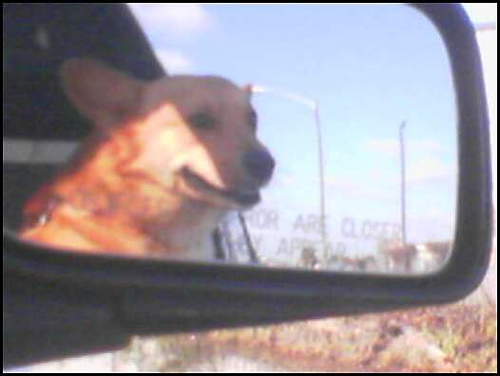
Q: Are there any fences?
A: No, there are no fences.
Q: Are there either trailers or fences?
A: No, there are no fences or trailers.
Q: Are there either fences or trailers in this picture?
A: No, there are no fences or trailers.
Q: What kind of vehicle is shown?
A: The vehicle is a car.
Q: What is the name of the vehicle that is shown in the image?
A: The vehicle is a car.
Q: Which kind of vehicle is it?
A: The vehicle is a car.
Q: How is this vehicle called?
A: This is a car.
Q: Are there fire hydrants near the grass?
A: No, there is a car near the grass.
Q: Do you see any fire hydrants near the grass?
A: No, there is a car near the grass.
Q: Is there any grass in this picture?
A: Yes, there is grass.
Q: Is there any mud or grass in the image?
A: Yes, there is grass.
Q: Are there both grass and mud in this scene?
A: No, there is grass but no mud.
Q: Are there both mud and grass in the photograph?
A: No, there is grass but no mud.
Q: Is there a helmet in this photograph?
A: No, there are no helmets.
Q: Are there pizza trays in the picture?
A: No, there are no pizza trays.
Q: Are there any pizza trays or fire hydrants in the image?
A: No, there are no pizza trays or fire hydrants.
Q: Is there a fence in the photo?
A: No, there are no fences.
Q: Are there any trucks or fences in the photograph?
A: No, there are no fences or trucks.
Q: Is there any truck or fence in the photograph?
A: No, there are no fences or trucks.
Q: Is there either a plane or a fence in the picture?
A: No, there are no fences or airplanes.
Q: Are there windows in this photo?
A: Yes, there is a window.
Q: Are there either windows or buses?
A: Yes, there is a window.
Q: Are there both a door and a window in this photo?
A: No, there is a window but no doors.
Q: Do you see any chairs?
A: No, there are no chairs.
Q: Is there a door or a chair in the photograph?
A: No, there are no chairs or doors.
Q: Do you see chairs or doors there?
A: No, there are no chairs or doors.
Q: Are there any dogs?
A: Yes, there is a dog.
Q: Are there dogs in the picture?
A: Yes, there is a dog.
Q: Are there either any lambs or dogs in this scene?
A: Yes, there is a dog.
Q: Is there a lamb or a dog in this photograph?
A: Yes, there is a dog.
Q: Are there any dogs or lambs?
A: Yes, there is a dog.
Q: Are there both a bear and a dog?
A: No, there is a dog but no bears.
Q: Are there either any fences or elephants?
A: No, there are no fences or elephants.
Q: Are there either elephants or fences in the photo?
A: No, there are no fences or elephants.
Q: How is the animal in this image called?
A: The animal is a dog.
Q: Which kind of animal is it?
A: The animal is a dog.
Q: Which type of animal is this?
A: This is a dog.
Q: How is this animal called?
A: This is a dog.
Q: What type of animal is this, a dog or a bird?
A: This is a dog.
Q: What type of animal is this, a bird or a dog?
A: This is a dog.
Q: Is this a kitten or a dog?
A: This is a dog.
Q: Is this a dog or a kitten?
A: This is a dog.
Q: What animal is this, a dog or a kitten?
A: This is a dog.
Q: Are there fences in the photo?
A: No, there are no fences.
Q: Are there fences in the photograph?
A: No, there are no fences.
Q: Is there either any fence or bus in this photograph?
A: No, there are no fences or buses.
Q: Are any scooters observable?
A: No, there are no scooters.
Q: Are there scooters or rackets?
A: No, there are no scooters or rackets.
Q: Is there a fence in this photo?
A: No, there are no fences.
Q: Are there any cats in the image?
A: No, there are no cats.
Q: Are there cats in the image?
A: No, there are no cats.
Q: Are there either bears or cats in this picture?
A: No, there are no cats or bears.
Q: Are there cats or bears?
A: No, there are no cats or bears.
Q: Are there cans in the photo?
A: No, there are no cans.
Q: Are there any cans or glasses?
A: No, there are no cans or glasses.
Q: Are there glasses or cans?
A: No, there are no cans or glasses.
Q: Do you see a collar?
A: Yes, there is a collar.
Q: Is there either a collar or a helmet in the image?
A: Yes, there is a collar.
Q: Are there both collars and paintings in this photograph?
A: No, there is a collar but no paintings.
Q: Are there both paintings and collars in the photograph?
A: No, there is a collar but no paintings.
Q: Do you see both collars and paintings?
A: No, there is a collar but no paintings.